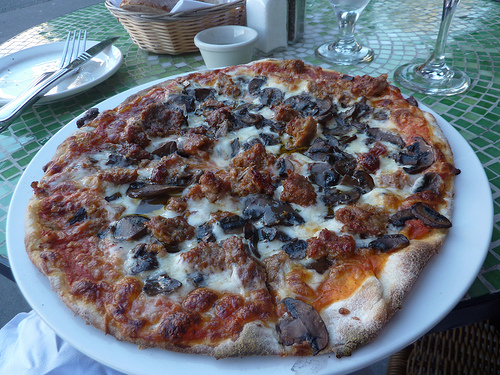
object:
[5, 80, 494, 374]
white plate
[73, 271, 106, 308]
cheese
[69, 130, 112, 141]
cheese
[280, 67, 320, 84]
cheese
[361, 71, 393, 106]
cheese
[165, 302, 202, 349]
cheese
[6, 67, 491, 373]
dish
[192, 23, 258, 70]
cup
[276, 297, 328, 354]
mushroom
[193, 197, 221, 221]
cheese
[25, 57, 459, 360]
pizza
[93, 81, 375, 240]
tomato sauce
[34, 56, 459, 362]
cheese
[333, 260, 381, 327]
crust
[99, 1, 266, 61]
wicker basket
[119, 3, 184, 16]
bread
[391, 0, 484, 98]
wine glass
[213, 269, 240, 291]
cheese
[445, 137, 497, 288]
plate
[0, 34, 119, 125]
knife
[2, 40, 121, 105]
plate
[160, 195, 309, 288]
sauce